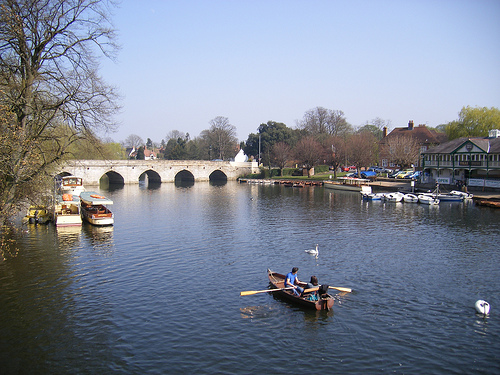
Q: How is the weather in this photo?
A: It is clear.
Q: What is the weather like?
A: It is clear.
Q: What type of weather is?
A: It is clear.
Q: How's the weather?
A: It is clear.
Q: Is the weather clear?
A: Yes, it is clear.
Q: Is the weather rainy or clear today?
A: It is clear.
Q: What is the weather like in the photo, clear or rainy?
A: It is clear.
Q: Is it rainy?
A: No, it is clear.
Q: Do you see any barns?
A: No, there are no barns.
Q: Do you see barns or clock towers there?
A: No, there are no barns or clock towers.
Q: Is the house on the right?
A: Yes, the house is on the right of the image.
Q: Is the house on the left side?
A: No, the house is on the right of the image.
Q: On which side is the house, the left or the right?
A: The house is on the right of the image.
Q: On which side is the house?
A: The house is on the right of the image.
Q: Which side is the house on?
A: The house is on the right of the image.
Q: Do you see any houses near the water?
A: Yes, there is a house near the water.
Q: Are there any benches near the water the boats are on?
A: No, there is a house near the water.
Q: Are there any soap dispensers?
A: No, there are no soap dispensers.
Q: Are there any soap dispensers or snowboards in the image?
A: No, there are no soap dispensers or snowboards.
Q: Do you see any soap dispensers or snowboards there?
A: No, there are no soap dispensers or snowboards.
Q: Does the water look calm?
A: Yes, the water is calm.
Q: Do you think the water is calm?
A: Yes, the water is calm.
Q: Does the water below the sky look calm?
A: Yes, the water is calm.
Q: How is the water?
A: The water is calm.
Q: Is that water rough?
A: No, the water is calm.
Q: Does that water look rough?
A: No, the water is calm.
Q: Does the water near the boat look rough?
A: No, the water is calm.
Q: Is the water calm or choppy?
A: The water is calm.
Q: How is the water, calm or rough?
A: The water is calm.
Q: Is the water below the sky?
A: Yes, the water is below the sky.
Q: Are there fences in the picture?
A: No, there are no fences.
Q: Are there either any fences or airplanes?
A: No, there are no fences or airplanes.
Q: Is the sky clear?
A: Yes, the sky is clear.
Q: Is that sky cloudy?
A: No, the sky is clear.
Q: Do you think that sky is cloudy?
A: No, the sky is clear.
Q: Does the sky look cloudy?
A: No, the sky is clear.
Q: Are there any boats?
A: Yes, there is a boat.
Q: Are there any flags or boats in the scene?
A: Yes, there is a boat.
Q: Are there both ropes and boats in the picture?
A: No, there is a boat but no ropes.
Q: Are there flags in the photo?
A: No, there are no flags.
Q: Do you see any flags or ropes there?
A: No, there are no flags or ropes.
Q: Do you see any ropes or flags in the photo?
A: No, there are no flags or ropes.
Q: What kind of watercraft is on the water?
A: The watercraft is a boat.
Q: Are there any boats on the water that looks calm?
A: Yes, there is a boat on the water.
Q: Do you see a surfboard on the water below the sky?
A: No, there is a boat on the water.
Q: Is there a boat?
A: Yes, there is a boat.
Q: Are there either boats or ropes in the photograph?
A: Yes, there is a boat.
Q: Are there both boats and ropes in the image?
A: No, there is a boat but no ropes.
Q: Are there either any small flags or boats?
A: Yes, there is a small boat.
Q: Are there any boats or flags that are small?
A: Yes, the boat is small.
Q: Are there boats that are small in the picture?
A: Yes, there is a small boat.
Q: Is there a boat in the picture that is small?
A: Yes, there is a boat that is small.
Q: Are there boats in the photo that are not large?
A: Yes, there is a small boat.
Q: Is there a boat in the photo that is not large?
A: Yes, there is a small boat.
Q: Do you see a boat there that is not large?
A: Yes, there is a small boat.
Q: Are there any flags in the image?
A: No, there are no flags.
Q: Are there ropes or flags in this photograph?
A: No, there are no flags or ropes.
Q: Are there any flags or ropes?
A: No, there are no flags or ropes.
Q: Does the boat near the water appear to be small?
A: Yes, the boat is small.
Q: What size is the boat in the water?
A: The boat is small.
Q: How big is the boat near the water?
A: The boat is small.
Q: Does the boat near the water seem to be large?
A: No, the boat is small.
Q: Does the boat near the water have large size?
A: No, the boat is small.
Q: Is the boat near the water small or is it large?
A: The boat is small.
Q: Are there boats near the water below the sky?
A: Yes, there is a boat near the water.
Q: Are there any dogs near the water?
A: No, there is a boat near the water.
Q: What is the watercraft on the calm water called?
A: The watercraft is a boat.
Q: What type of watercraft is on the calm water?
A: The watercraft is a boat.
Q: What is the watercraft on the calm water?
A: The watercraft is a boat.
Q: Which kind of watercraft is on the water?
A: The watercraft is a boat.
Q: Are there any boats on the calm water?
A: Yes, there is a boat on the water.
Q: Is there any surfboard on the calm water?
A: No, there is a boat on the water.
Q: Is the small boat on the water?
A: Yes, the boat is on the water.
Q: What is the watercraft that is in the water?
A: The watercraft is a boat.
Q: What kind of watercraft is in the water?
A: The watercraft is a boat.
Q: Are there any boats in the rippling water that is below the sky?
A: Yes, there is a boat in the water.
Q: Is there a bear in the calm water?
A: No, there is a boat in the water.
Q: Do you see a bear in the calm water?
A: No, there is a boat in the water.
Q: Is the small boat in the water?
A: Yes, the boat is in the water.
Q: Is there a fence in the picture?
A: No, there are no fences.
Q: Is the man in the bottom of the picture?
A: Yes, the man is in the bottom of the image.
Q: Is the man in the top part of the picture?
A: No, the man is in the bottom of the image.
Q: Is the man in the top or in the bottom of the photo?
A: The man is in the bottom of the image.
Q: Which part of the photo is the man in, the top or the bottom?
A: The man is in the bottom of the image.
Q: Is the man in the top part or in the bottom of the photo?
A: The man is in the bottom of the image.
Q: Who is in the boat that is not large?
A: The man is in the boat.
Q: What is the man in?
A: The man is in the boat.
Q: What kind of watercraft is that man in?
A: The man is in the boat.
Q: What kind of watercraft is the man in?
A: The man is in the boat.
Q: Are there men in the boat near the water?
A: Yes, there is a man in the boat.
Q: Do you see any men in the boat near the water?
A: Yes, there is a man in the boat.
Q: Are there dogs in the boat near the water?
A: No, there is a man in the boat.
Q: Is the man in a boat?
A: Yes, the man is in a boat.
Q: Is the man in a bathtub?
A: No, the man is in a boat.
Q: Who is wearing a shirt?
A: The man is wearing a shirt.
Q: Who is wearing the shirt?
A: The man is wearing a shirt.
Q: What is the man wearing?
A: The man is wearing a shirt.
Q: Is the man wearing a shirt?
A: Yes, the man is wearing a shirt.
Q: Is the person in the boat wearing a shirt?
A: Yes, the man is wearing a shirt.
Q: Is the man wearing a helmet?
A: No, the man is wearing a shirt.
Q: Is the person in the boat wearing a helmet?
A: No, the man is wearing a shirt.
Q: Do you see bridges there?
A: Yes, there is a bridge.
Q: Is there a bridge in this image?
A: Yes, there is a bridge.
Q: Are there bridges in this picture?
A: Yes, there is a bridge.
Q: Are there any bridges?
A: Yes, there is a bridge.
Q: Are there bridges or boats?
A: Yes, there is a bridge.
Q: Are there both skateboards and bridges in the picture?
A: No, there is a bridge but no skateboards.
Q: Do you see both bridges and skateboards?
A: No, there is a bridge but no skateboards.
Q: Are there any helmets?
A: No, there are no helmets.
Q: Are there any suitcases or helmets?
A: No, there are no helmets or suitcases.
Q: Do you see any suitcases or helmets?
A: No, there are no helmets or suitcases.